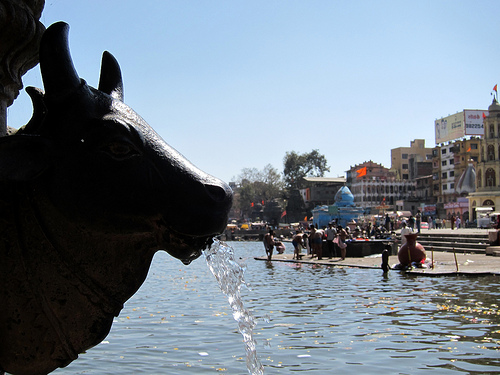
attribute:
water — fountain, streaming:
[204, 235, 266, 374]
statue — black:
[0, 20, 233, 374]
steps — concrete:
[413, 232, 491, 256]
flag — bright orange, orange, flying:
[355, 165, 370, 179]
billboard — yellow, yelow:
[433, 110, 467, 144]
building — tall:
[434, 136, 484, 218]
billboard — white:
[462, 108, 489, 136]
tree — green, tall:
[282, 146, 329, 218]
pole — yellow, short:
[406, 245, 414, 272]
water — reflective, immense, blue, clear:
[49, 238, 500, 374]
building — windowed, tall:
[464, 87, 499, 228]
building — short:
[346, 174, 416, 217]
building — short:
[294, 175, 346, 215]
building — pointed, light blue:
[309, 184, 368, 228]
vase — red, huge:
[398, 230, 430, 266]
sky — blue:
[6, 0, 498, 188]